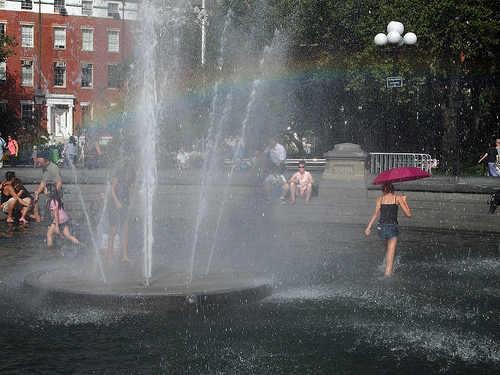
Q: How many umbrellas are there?
A: One.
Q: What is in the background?
A: Trees.